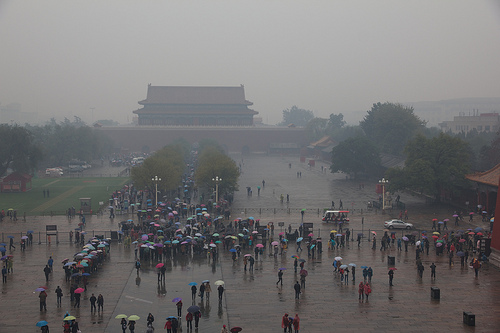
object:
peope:
[272, 265, 285, 285]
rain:
[0, 0, 499, 332]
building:
[129, 82, 259, 125]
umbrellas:
[212, 277, 225, 286]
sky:
[1, 0, 499, 127]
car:
[381, 216, 415, 230]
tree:
[326, 134, 387, 182]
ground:
[1, 153, 499, 332]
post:
[380, 184, 385, 212]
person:
[329, 254, 343, 273]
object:
[47, 224, 59, 235]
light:
[376, 176, 389, 209]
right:
[248, 0, 499, 332]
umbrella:
[255, 242, 265, 249]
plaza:
[229, 148, 436, 208]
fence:
[232, 205, 378, 215]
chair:
[324, 215, 351, 220]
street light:
[210, 175, 223, 206]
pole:
[153, 183, 158, 208]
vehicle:
[318, 209, 351, 225]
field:
[0, 175, 132, 216]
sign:
[301, 222, 314, 230]